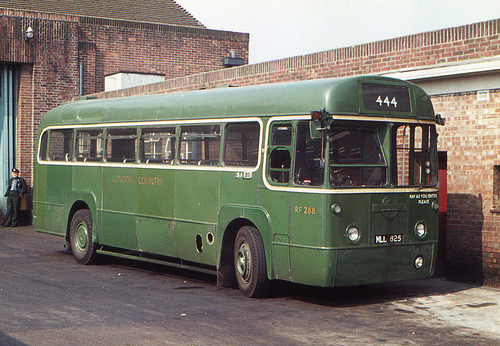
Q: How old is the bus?
A: Very old.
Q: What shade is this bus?
A: Green.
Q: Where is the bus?
A: Parked.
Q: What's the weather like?
A: Overcast.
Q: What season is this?
A: Fall.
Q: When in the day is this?
A: Afternoon.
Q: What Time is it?
A: 3:34 PM.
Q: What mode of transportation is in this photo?
A: A bus.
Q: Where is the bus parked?
A: On a road.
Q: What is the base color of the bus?
A: Green.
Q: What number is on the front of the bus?
A: 444.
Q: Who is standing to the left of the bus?
A: No one.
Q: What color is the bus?
A: Green.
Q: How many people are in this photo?
A: Zero.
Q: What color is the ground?
A: Grey.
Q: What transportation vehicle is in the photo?
A: Bus.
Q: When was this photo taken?
A: Daytime.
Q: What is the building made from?
A: Brick.